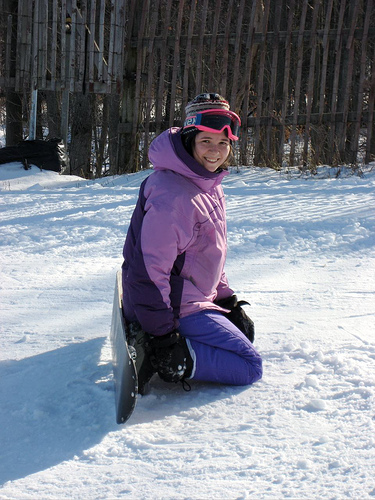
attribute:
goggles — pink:
[184, 107, 241, 134]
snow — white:
[1, 90, 374, 498]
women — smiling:
[120, 90, 264, 394]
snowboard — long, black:
[85, 259, 162, 438]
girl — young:
[119, 86, 308, 383]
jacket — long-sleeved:
[116, 127, 238, 339]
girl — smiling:
[82, 102, 274, 373]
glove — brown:
[212, 288, 253, 339]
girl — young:
[84, 73, 277, 429]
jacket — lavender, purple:
[111, 124, 245, 344]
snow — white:
[185, 391, 338, 467]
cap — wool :
[184, 91, 231, 114]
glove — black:
[153, 327, 193, 383]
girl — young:
[112, 88, 263, 390]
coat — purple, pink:
[122, 143, 229, 328]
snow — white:
[2, 173, 365, 496]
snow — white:
[2, 495, 373, 497]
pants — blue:
[180, 311, 261, 387]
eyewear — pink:
[153, 127, 269, 149]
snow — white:
[4, 395, 372, 495]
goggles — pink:
[184, 111, 245, 139]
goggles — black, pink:
[187, 91, 271, 145]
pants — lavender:
[176, 309, 263, 384]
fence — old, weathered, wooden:
[0, 0, 372, 177]